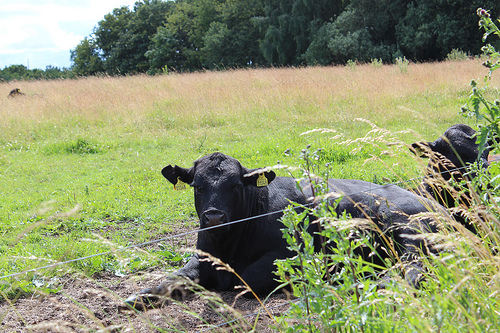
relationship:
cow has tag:
[155, 152, 466, 296] [254, 173, 269, 187]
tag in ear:
[254, 173, 269, 187] [242, 163, 280, 189]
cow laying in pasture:
[155, 152, 466, 296] [3, 56, 499, 332]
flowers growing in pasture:
[272, 147, 348, 263] [3, 56, 499, 332]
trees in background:
[252, 0, 403, 63] [13, 57, 499, 61]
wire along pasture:
[0, 157, 497, 281] [3, 56, 499, 332]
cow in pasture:
[405, 111, 499, 215] [3, 56, 499, 332]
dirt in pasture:
[7, 282, 261, 332] [3, 56, 499, 332]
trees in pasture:
[252, 0, 403, 63] [3, 56, 499, 332]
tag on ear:
[254, 173, 269, 187] [242, 163, 280, 189]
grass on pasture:
[0, 56, 496, 121] [3, 56, 499, 332]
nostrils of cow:
[203, 213, 228, 224] [155, 152, 466, 296]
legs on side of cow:
[125, 241, 325, 309] [155, 152, 466, 296]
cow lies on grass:
[155, 152, 466, 296] [0, 56, 496, 121]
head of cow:
[158, 150, 285, 239] [155, 152, 466, 296]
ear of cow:
[242, 163, 280, 189] [155, 152, 466, 296]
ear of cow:
[156, 163, 192, 190] [155, 152, 466, 296]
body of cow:
[245, 169, 465, 297] [155, 152, 466, 296]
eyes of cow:
[190, 180, 243, 197] [155, 152, 466, 296]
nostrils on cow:
[203, 213, 228, 224] [155, 152, 466, 296]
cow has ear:
[155, 152, 466, 296] [242, 163, 280, 189]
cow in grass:
[405, 111, 499, 215] [0, 56, 496, 121]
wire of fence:
[0, 157, 497, 281] [1, 154, 498, 327]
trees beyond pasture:
[252, 0, 403, 63] [3, 56, 499, 332]